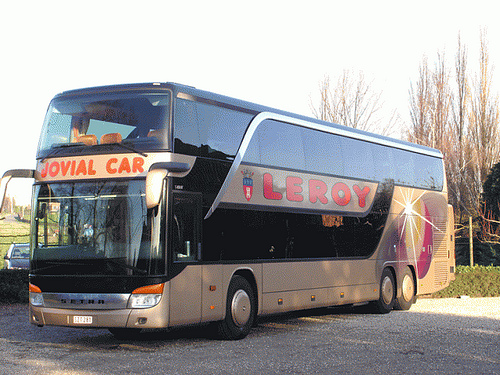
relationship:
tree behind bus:
[307, 68, 399, 142] [27, 84, 458, 333]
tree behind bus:
[399, 43, 493, 277] [27, 84, 458, 333]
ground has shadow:
[0, 284, 499, 374] [1, 299, 499, 374]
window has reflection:
[28, 181, 161, 271] [44, 184, 151, 264]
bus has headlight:
[27, 84, 458, 333] [27, 288, 47, 308]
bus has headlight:
[27, 84, 458, 333] [130, 293, 163, 310]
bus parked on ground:
[27, 84, 458, 333] [0, 284, 499, 374]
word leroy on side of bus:
[260, 169, 370, 213] [27, 84, 458, 333]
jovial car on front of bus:
[37, 158, 148, 179] [27, 84, 458, 333]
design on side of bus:
[241, 171, 257, 202] [27, 84, 458, 333]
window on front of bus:
[28, 181, 161, 271] [27, 84, 458, 333]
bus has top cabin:
[27, 84, 458, 333] [40, 88, 458, 212]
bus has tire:
[27, 84, 458, 333] [221, 279, 256, 339]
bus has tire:
[27, 84, 458, 333] [376, 269, 397, 315]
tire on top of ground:
[392, 266, 419, 312] [0, 284, 499, 374]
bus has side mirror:
[27, 84, 458, 333] [142, 160, 191, 208]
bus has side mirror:
[27, 84, 458, 333] [1, 166, 38, 220]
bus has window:
[27, 84, 458, 333] [28, 181, 161, 271]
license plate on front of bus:
[72, 313, 94, 324] [27, 84, 458, 333]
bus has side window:
[27, 84, 458, 333] [177, 105, 252, 155]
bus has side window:
[27, 84, 458, 333] [172, 191, 205, 259]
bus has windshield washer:
[27, 84, 458, 333] [28, 255, 86, 278]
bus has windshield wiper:
[27, 84, 458, 333] [92, 253, 147, 277]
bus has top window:
[27, 84, 458, 333] [40, 96, 174, 150]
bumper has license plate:
[26, 307, 166, 329] [72, 313, 94, 324]